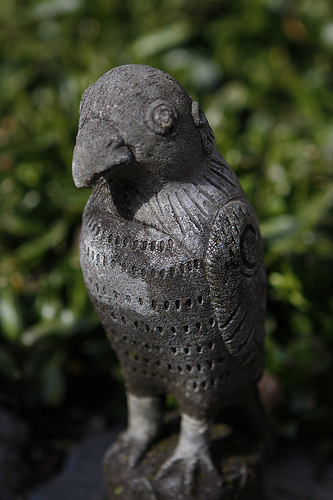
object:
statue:
[68, 65, 269, 480]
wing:
[204, 197, 264, 381]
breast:
[79, 217, 206, 335]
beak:
[72, 123, 130, 191]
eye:
[147, 99, 178, 136]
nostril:
[105, 134, 117, 150]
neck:
[172, 164, 215, 177]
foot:
[153, 413, 227, 492]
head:
[71, 64, 219, 190]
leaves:
[0, 0, 333, 455]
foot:
[102, 399, 161, 468]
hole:
[193, 319, 203, 330]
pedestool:
[101, 425, 264, 499]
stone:
[106, 74, 146, 119]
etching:
[220, 220, 263, 287]